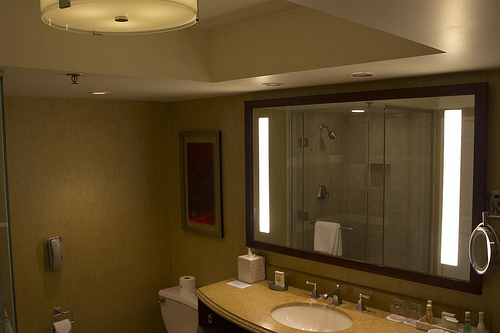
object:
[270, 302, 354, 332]
sink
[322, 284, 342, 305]
faucet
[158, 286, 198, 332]
white toilet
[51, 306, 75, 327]
holder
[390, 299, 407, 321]
cup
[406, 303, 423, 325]
cup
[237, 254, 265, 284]
tissue box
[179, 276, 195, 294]
paper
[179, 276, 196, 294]
roll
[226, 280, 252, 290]
rd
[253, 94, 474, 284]
reflection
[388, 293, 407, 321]
glasses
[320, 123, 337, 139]
shower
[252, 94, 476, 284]
mirror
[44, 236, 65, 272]
phone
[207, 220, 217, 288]
toilet paper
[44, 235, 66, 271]
yellow letter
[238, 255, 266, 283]
box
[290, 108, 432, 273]
glass doors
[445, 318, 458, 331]
soap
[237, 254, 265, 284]
roll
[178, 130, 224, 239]
painting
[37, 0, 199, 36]
lights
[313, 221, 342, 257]
towel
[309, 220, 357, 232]
rack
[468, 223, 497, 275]
mirror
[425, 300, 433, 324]
bottle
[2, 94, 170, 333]
wall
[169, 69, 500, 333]
wall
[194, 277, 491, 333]
counter